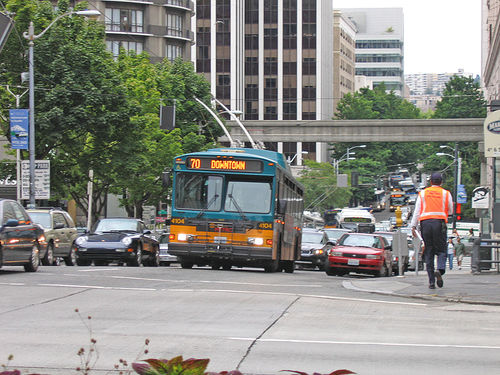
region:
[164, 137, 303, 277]
a vehicle on the road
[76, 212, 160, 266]
a vehicle on the road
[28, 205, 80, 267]
a vehicle on the road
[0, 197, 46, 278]
a vehicle on the road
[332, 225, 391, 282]
a vehicle on the road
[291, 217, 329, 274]
a vehicle on the road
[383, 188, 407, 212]
a vehicle on the road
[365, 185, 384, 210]
a vehicle on the road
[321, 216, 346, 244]
a vehicle on the road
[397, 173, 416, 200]
a vehicle on the road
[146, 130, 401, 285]
Many cars and buses on road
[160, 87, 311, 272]
A trolley bus number 70 is going to downtown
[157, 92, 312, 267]
A trolley green and yellow bus is going downtown.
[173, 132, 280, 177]
A lit up neon bus sign says number 70 downtown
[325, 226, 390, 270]
A red car is parked next to curb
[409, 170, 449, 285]
A man wearing an orange reflector coat is walking on the sidewalk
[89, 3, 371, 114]
Many highrise buildings are in the background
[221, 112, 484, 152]
The monor rail a form of light rail is in the air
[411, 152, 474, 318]
Many people are walking on the sidewalk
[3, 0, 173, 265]
Many trees, cars, signs and a light post are in the background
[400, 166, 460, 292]
a person in an orange vest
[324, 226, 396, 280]
a red colored car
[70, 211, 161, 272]
a black colored Porsche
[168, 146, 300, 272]
a blue and orange colored bus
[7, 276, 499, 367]
a paved road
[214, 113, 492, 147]
an overpass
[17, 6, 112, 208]
a lamp post on a road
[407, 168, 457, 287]
a person wearing a hat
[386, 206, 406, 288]
a yellow parking meter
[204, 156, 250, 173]
the word downtown displayed on a bus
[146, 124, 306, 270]
city bus driving down street.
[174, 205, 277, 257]
head lights on the front of a bus.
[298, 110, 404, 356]
city traffic driving past tall buildings.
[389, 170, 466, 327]
person in safety vest walking.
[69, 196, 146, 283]
small car driving past tall buildings.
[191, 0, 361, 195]
tall building lining city street.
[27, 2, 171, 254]
green leafy trees lining city street.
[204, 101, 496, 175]
cement bridge crossing over city street.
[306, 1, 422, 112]
tall buildings near city street.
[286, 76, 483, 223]
leafy trees behind city traffic.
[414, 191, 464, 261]
Person wearing orange vest.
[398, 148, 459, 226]
Person wearing dark hat.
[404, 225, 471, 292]
Person wearing dark pants.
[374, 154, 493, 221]
Person walking on sidewalk.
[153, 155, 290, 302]
Front of bus is yellow and blue.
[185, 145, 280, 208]
Bus has yellow writing on it.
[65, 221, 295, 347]
White lines in road.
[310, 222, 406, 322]
Red car near bus.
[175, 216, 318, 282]
Headlights are on on bus.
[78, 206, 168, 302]
Small black car near bus.